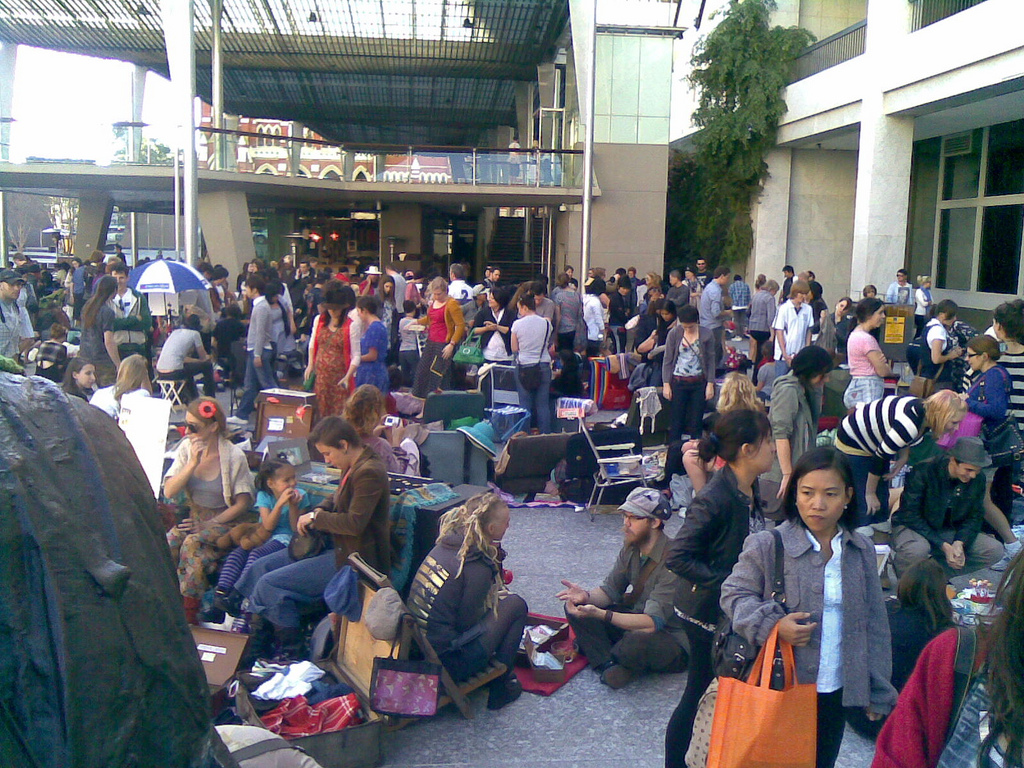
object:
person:
[224, 278, 282, 425]